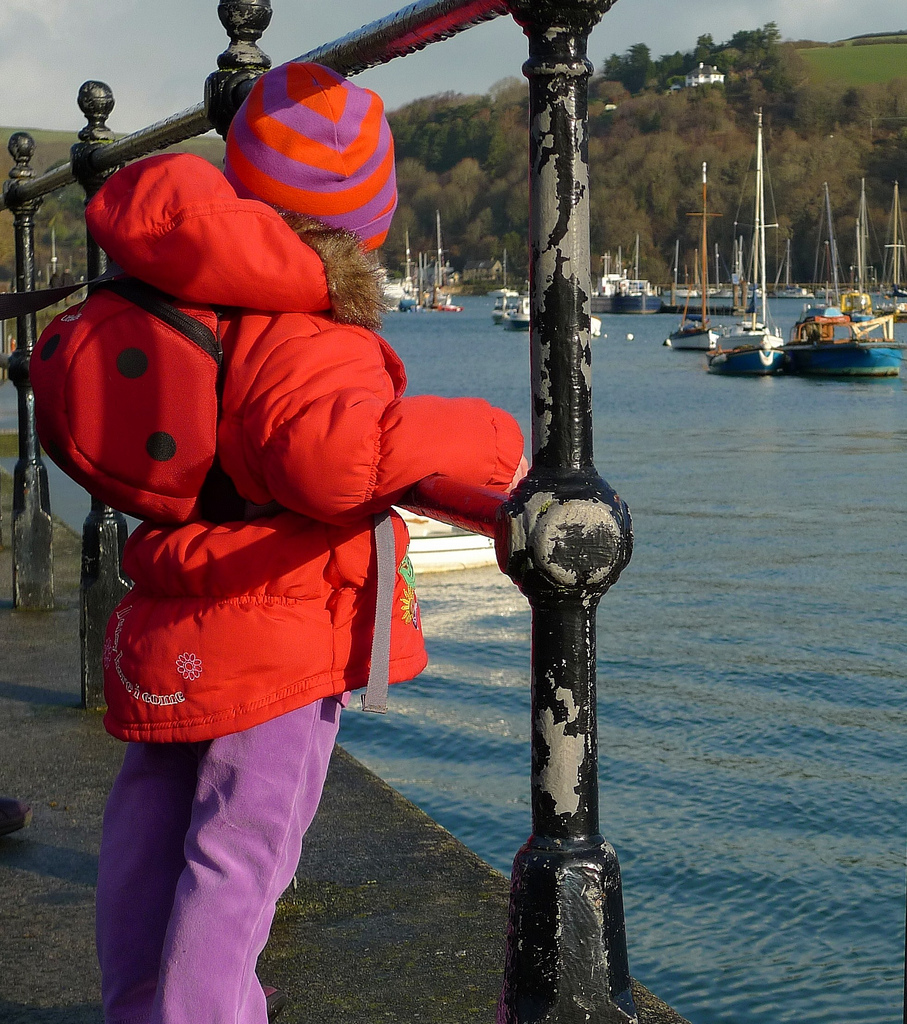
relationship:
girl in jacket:
[29, 61, 529, 1020] [58, 165, 539, 738]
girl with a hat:
[29, 61, 529, 1020] [223, 56, 414, 247]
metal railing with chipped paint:
[513, 6, 651, 1008] [530, 669, 627, 845]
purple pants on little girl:
[104, 677, 346, 1018] [37, 59, 579, 1007]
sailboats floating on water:
[667, 84, 904, 410] [347, 277, 896, 1007]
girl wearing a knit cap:
[41, 62, 527, 1020] [220, 62, 403, 249]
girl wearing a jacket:
[29, 61, 529, 1020] [77, 150, 515, 743]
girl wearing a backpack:
[29, 61, 529, 1020] [31, 268, 230, 521]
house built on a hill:
[687, 59, 729, 90] [732, 34, 875, 264]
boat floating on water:
[710, 316, 787, 378] [629, 372, 866, 1015]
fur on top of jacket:
[272, 203, 398, 334] [220, 168, 526, 723]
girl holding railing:
[29, 61, 529, 1020] [504, 6, 635, 1020]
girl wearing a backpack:
[29, 61, 529, 1020] [24, 268, 226, 535]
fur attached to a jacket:
[300, 220, 395, 325] [58, 165, 539, 738]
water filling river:
[633, 390, 845, 1018] [633, 371, 880, 1020]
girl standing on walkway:
[29, 61, 529, 1020] [3, 463, 95, 1010]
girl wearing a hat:
[29, 61, 529, 1020] [232, 64, 398, 258]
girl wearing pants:
[29, 61, 529, 1020] [98, 702, 345, 1016]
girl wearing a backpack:
[41, 62, 527, 1020] [31, 305, 223, 521]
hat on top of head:
[246, 67, 387, 225] [229, 70, 403, 295]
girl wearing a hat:
[29, 61, 529, 1020] [246, 67, 387, 225]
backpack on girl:
[41, 268, 238, 541] [29, 61, 529, 1020]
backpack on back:
[41, 268, 238, 541] [147, 314, 247, 597]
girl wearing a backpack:
[29, 61, 529, 1020] [41, 268, 238, 541]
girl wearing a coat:
[29, 61, 529, 1020] [239, 364, 428, 510]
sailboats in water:
[779, 318, 879, 375] [680, 408, 838, 571]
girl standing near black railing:
[29, 61, 529, 1020] [514, 714, 675, 1024]